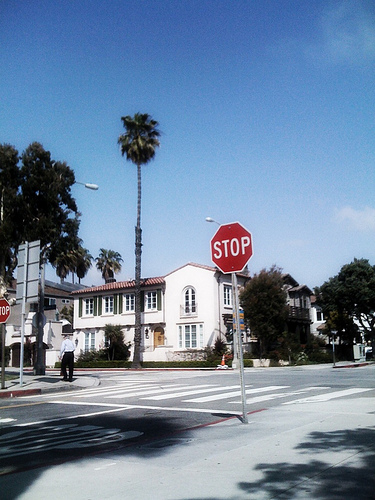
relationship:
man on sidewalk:
[59, 330, 76, 382] [1, 373, 99, 395]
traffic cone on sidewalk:
[219, 353, 227, 365] [150, 367, 212, 372]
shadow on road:
[231, 425, 362, 495] [2, 363, 374, 500]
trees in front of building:
[238, 256, 361, 363] [72, 260, 237, 363]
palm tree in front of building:
[117, 112, 159, 369] [69, 261, 249, 361]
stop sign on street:
[209, 221, 251, 422] [2, 399, 344, 471]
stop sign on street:
[0, 297, 9, 389] [2, 399, 344, 471]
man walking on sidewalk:
[59, 335, 76, 382] [0, 374, 101, 391]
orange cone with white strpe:
[219, 353, 226, 365] [220, 356, 226, 361]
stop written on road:
[0, 425, 144, 459] [2, 363, 374, 500]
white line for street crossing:
[137, 384, 252, 400] [12, 380, 362, 414]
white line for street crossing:
[181, 392, 239, 404] [12, 380, 362, 414]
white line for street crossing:
[101, 382, 216, 396] [12, 380, 362, 414]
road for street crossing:
[2, 382, 363, 472] [12, 380, 362, 414]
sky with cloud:
[259, 3, 363, 251] [330, 198, 363, 241]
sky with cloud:
[259, 3, 363, 251] [270, 5, 364, 71]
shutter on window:
[96, 296, 102, 315] [79, 294, 96, 316]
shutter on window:
[117, 292, 123, 313] [100, 294, 112, 314]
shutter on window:
[157, 286, 161, 311] [124, 295, 134, 314]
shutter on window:
[156, 289, 163, 309] [144, 292, 158, 313]